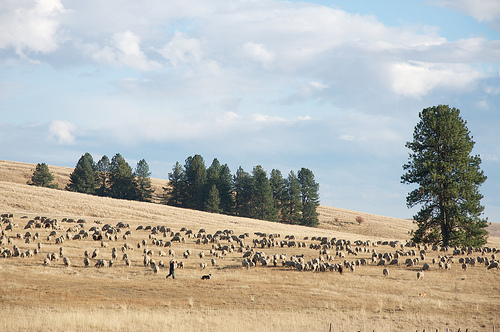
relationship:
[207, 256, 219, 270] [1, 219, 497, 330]
sheep on field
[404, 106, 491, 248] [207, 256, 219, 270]
tree by sheep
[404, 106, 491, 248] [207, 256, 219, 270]
tree behind sheep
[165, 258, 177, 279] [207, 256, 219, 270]
person by sheep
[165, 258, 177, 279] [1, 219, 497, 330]
person in field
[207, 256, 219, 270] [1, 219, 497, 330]
sheep in field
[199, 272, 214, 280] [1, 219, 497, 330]
dog in field